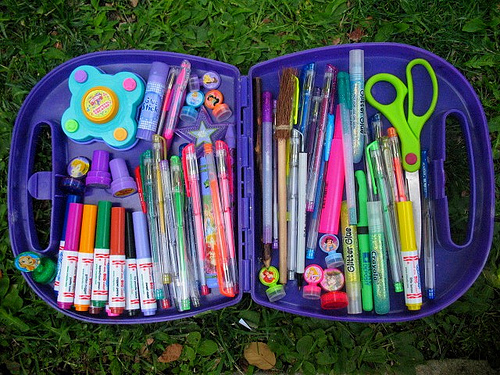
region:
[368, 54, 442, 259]
scissors in the pencil box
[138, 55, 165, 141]
glue stick in the pencil box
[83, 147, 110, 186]
ink stamp in the pencil box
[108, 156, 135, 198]
ink stamp in the pencil box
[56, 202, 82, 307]
marker in the pencil box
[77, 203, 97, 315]
marker in the pencil box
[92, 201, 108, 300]
marker in the pencil box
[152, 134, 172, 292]
pen in the pencil box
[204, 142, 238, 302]
pens in the pencil box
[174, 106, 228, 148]
star on the pencil box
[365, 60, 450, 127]
green handle on siccors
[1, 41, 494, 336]
a purple box full of school stuff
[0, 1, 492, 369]
a purple b ox in the grass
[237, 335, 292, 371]
a brown leave in the grass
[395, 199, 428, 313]
a yellow mark in box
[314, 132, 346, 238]
a bright pink marker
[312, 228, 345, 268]
a blue stamp with a sticker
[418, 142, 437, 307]
a blue ink pen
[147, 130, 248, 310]
a pile of lead pencils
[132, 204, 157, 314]
a light blue marker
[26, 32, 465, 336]
There are items in the chest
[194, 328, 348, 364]
Grass is in the shot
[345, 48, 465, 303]
Scissors are in the chest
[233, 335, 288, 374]
Brown leaf on the ground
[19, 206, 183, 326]
These are markers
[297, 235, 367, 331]
Stamps in the chest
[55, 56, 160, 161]
Light blue is the color of the item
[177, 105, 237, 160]
A star in the chest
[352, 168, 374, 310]
A green pen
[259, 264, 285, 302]
a green stamper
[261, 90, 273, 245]
A clear purple pen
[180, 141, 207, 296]
A pink gel pen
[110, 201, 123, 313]
A red marker in a case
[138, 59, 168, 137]
A purple marker stick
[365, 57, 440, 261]
A green pair of scissors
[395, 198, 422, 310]
A yellow marker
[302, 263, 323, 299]
A pink stamp in a container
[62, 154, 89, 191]
A dark colored stamp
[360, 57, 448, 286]
a pair of scissors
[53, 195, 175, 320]
a row of markers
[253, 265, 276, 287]
a picture of Ariel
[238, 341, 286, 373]
brown leaf on the ground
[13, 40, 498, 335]
art box laying open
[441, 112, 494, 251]
handle on the box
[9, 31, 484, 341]
art box laying in the grass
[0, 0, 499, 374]
green grass on the ground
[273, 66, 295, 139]
bristles on the paintbrush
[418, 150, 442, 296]
blue pen laying in the box